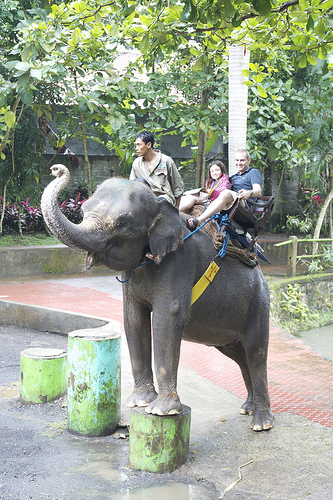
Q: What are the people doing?
A: Riding an elephant.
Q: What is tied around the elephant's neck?
A: A blue cord used to tie the seat onto its back.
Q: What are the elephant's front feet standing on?
A: A green post.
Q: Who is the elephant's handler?
A: The man in front.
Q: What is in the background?
A: Trees.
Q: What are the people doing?
A: Riding a elephant.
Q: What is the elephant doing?
A: Standing on a block.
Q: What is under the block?
A: Concrete walk.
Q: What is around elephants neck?
A: Blue rope.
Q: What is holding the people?
A: A wooden chair.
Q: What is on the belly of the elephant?
A: A yellow strap.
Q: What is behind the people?
A: Trees and a building.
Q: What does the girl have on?
A: A pink top.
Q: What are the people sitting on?
A: An elephant.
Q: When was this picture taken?
A: Daytime.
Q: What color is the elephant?
A: Gray.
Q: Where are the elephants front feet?
A: On a concrete post.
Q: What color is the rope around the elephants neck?
A: Blue.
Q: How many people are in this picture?
A: 3.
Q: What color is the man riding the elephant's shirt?
A: Blue.